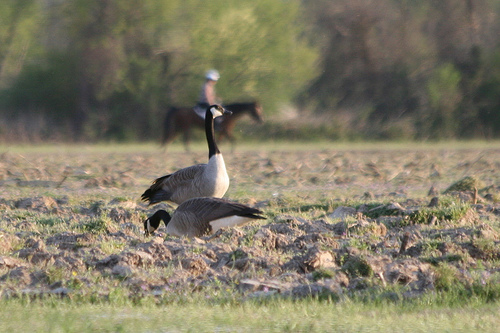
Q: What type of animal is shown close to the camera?
A: Geese.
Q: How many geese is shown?
A: 2.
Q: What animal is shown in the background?
A: Horse.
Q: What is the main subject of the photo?
A: Geese.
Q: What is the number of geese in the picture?
A: 2.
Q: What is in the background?
A: Man riding a horse.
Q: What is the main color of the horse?
A: Brown.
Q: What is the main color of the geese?
A: Grey.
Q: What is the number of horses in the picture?
A: 1.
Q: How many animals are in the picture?
A: 3.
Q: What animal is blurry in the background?
A: Horse.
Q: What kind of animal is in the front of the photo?
A: Ducks.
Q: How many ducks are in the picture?
A: 2.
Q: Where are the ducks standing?
A: In the dirt.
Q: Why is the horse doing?
A: Carrying a rider.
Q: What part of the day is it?
A: Daytime.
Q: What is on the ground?
A: Dirt and grass.